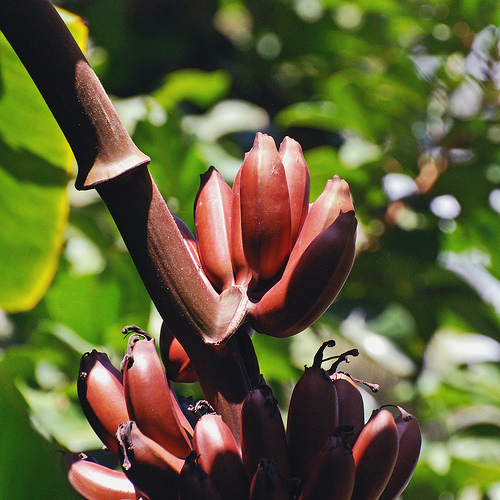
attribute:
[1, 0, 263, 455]
branch — brown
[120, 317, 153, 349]
stem — brown, small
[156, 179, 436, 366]
bananas — red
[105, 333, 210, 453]
banana — dried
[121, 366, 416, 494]
bananas — small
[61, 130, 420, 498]
bananas — red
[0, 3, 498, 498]
forest — green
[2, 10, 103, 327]
leaf — yellow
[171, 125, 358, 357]
bananas — red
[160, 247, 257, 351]
branch — curved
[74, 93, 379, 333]
bananas — red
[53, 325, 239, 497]
plant — opening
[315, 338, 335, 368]
flowers — black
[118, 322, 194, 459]
banana — brown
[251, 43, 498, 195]
leaves — green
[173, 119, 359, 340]
bananas — red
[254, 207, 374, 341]
banana — red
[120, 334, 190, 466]
banana — red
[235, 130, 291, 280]
banana — red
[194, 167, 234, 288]
banana — red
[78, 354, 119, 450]
banana — red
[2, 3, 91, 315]
leaf — green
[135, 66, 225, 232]
leaf — green